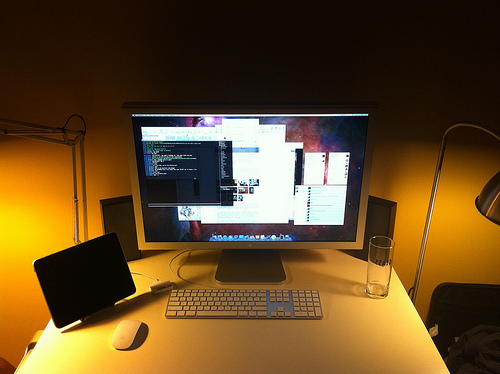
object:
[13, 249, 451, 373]
desk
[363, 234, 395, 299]
glass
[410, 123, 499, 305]
floor lamp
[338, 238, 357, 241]
clock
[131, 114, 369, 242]
monitor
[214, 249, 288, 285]
base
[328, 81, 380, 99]
corner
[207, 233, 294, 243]
dock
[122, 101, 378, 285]
computer monitor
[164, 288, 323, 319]
computer keyboard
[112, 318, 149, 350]
computer mouse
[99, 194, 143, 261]
computer speaker